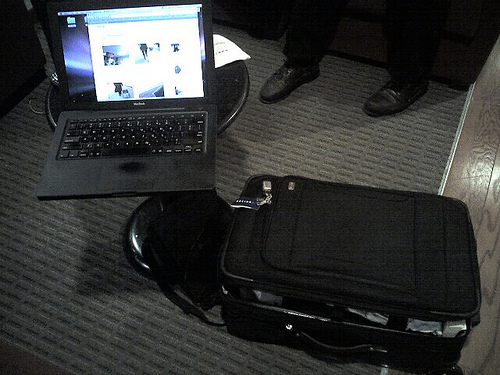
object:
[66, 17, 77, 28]
icon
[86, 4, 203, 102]
page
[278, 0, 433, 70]
pants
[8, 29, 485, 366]
ground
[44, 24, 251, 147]
table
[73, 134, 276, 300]
shadow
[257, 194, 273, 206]
zipper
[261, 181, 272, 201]
lock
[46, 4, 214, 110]
screen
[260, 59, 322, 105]
shoes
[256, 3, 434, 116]
person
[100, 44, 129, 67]
pictures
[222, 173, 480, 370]
luggage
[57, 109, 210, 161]
keyboard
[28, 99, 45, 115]
cord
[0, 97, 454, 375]
carpet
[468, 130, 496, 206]
wood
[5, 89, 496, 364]
floor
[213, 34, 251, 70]
paper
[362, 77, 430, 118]
black shoes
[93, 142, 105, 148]
keys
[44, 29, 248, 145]
tray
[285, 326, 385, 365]
handle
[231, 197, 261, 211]
tags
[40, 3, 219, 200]
computer